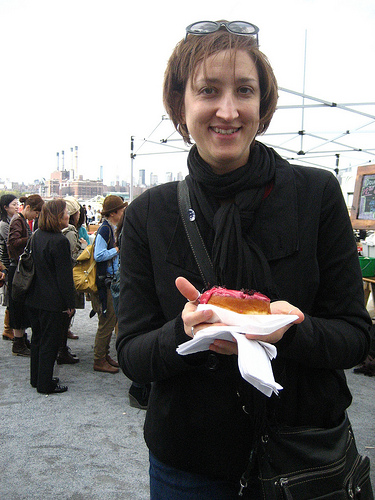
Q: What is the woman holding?
A: A donut.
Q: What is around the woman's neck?
A: A scarf.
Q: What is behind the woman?
A: Scaffolding.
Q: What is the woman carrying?
A: A purse.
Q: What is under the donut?
A: A napkin.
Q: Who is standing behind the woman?
A: A crowd.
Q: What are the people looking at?
A: The crowd.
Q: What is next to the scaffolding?
A: A building.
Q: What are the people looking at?
A: A large television.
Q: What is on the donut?
A: Frosting.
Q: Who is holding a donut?
A: A woman.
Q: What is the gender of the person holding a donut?
A: Female.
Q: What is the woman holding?
A: A donut.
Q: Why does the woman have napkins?
A: The donut is messy.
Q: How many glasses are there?
A: One.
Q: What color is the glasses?
A: Black.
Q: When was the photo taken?
A: Daytime.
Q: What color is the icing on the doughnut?
A: Pink.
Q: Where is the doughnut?
A: In the woman's hand.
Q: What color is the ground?
A: Gray.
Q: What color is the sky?
A: White.